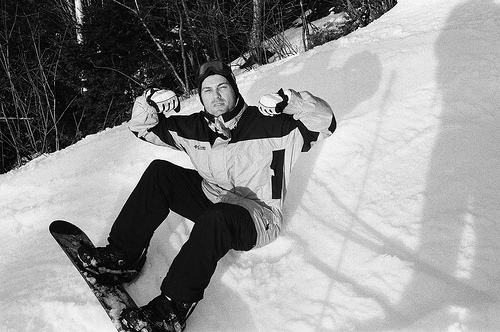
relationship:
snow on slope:
[373, 134, 499, 241] [339, 33, 490, 328]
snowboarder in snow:
[40, 51, 349, 330] [3, 2, 495, 326]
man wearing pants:
[98, 20, 345, 267] [77, 149, 274, 328]